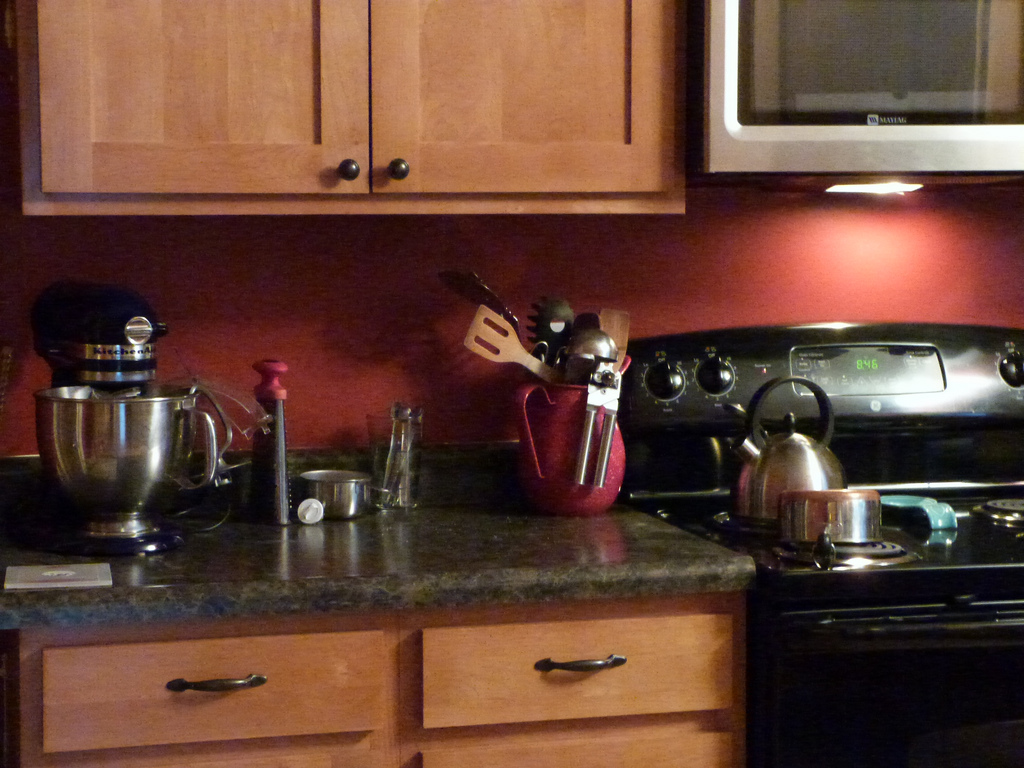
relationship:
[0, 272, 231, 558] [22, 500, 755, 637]
bowl on counter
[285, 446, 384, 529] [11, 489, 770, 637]
bowl on counter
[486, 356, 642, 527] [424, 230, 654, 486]
container full of utensils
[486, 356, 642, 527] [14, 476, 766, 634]
container on counter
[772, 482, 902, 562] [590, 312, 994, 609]
pan on stovetop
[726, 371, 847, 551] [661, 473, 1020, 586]
kettle on stovetop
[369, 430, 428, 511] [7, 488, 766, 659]
glass on counter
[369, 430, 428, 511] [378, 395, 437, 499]
glass with spoons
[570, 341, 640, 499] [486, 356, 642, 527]
can opener in container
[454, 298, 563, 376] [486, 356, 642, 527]
spatula in container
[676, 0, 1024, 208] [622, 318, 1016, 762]
microwave above stovetop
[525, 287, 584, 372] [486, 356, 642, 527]
server in container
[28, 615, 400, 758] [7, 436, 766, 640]
drawer under counter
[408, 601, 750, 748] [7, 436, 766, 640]
drawer under counter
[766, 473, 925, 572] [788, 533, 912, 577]
pan on burner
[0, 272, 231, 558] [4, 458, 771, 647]
bowl on countertop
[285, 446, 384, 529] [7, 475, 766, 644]
bowl on countertop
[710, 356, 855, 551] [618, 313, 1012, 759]
kettle on stove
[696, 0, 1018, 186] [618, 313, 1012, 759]
microwave above stove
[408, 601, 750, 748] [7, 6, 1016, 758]
drawer in kitchen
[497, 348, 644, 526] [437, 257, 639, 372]
container holding utensils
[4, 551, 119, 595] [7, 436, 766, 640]
case on counter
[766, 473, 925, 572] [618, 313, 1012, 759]
pan sitting on stove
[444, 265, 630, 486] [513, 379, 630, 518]
utensils in jug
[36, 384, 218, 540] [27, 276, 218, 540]
bowl on mixer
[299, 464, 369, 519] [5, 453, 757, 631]
bowl on counter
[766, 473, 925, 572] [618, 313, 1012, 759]
pan on stove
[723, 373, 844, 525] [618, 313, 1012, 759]
tea kettle on stove